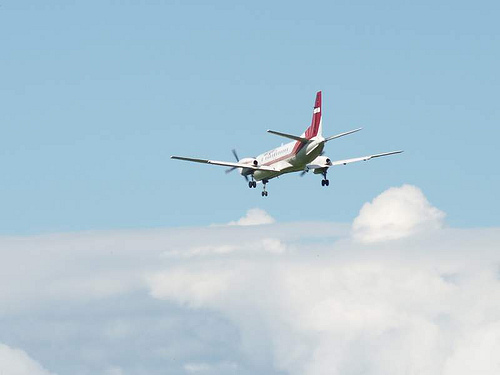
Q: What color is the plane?
A: Red and white.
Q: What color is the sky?
A: Blue.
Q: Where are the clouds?
A: Under the plane.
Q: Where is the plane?
A: In the air.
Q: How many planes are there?
A: 1.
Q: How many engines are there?
A: 2.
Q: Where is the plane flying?
A: In the sky.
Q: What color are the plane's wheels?
A: Black.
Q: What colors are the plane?
A: Red and white.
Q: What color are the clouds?
A: White.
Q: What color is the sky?
A: Blue.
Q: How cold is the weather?
A: 40 degrees Fahrenheit.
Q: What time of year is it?
A: Late autumn.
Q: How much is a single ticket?
A: $200.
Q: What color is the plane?
A: Red and White.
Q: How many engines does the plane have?
A: Two.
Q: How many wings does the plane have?
A: Two.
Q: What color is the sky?
A: Blue.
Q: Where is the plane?
A: In the sky.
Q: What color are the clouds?
A: White.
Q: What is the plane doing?
A: Flying.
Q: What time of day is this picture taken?
A: In the daytime.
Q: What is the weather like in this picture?
A: Clear and sunny.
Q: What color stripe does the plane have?
A: Red.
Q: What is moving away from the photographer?
A: A plane.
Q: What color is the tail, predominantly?
A: Red.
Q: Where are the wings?
A: They are connected to either side of the plane's underbelly.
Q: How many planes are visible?
A: Just one.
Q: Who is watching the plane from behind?
A: The photographer.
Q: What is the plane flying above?
A: The clouds.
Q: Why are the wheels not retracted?
A: It may be headed for land.